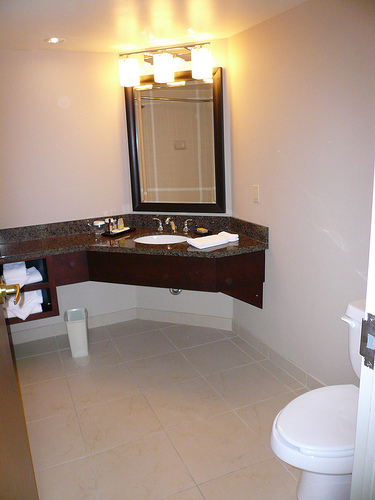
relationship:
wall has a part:
[260, 15, 348, 387] [307, 179, 336, 211]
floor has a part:
[11, 318, 327, 454] [106, 380, 179, 429]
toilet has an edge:
[265, 299, 373, 492] [257, 381, 305, 500]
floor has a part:
[11, 318, 327, 454] [307, 179, 336, 211]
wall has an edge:
[260, 15, 348, 387] [227, 6, 300, 41]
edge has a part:
[227, 6, 300, 41] [257, 15, 276, 34]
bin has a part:
[63, 307, 97, 362] [71, 327, 84, 345]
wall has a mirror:
[260, 15, 348, 387] [117, 68, 233, 216]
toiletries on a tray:
[93, 218, 130, 237] [104, 227, 138, 237]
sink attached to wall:
[133, 212, 193, 247] [260, 15, 348, 387]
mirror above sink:
[117, 68, 233, 216] [133, 212, 193, 247]